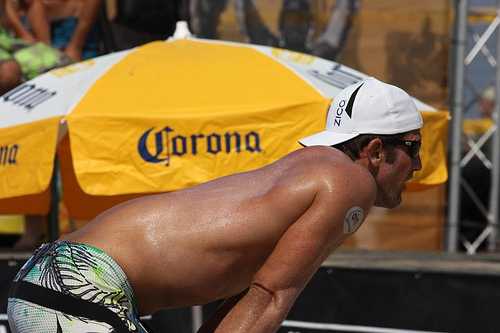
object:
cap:
[298, 77, 424, 148]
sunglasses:
[385, 139, 422, 158]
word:
[138, 124, 260, 167]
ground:
[425, 252, 437, 267]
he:
[8, 76, 423, 332]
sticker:
[343, 206, 364, 235]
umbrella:
[0, 20, 450, 198]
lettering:
[334, 100, 345, 126]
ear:
[365, 138, 381, 167]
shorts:
[0, 240, 142, 332]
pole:
[446, 0, 467, 255]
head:
[323, 77, 423, 211]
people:
[0, 0, 102, 82]